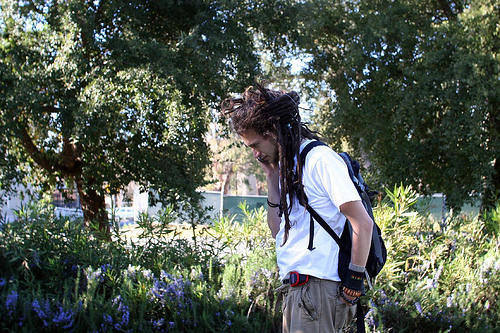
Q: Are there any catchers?
A: No, there are no catchers.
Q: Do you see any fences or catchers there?
A: No, there are no catchers or fences.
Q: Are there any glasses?
A: No, there are no glasses.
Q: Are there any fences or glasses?
A: No, there are no glasses or fences.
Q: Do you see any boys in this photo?
A: No, there are no boys.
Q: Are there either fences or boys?
A: No, there are no boys or fences.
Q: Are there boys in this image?
A: No, there are no boys.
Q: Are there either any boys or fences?
A: No, there are no boys or fences.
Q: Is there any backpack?
A: Yes, there is a backpack.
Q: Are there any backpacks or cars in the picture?
A: Yes, there is a backpack.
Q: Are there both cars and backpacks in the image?
A: No, there is a backpack but no cars.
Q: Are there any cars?
A: No, there are no cars.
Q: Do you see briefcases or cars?
A: No, there are no cars or briefcases.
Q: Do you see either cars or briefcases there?
A: No, there are no cars or briefcases.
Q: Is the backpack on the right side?
A: Yes, the backpack is on the right of the image.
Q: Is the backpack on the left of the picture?
A: No, the backpack is on the right of the image.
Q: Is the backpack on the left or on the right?
A: The backpack is on the right of the image.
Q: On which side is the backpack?
A: The backpack is on the right of the image.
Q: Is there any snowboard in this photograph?
A: No, there are no snowboards.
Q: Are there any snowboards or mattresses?
A: No, there are no snowboards or mattresses.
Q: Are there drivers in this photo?
A: No, there are no drivers.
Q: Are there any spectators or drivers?
A: No, there are no drivers or spectators.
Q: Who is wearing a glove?
A: The man is wearing a glove.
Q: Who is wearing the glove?
A: The man is wearing a glove.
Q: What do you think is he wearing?
A: The man is wearing a glove.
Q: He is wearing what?
A: The man is wearing a glove.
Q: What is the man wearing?
A: The man is wearing a glove.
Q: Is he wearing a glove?
A: Yes, the man is wearing a glove.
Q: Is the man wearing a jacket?
A: No, the man is wearing a glove.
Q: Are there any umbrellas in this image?
A: No, there are no umbrellas.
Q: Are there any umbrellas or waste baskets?
A: No, there are no umbrellas or waste baskets.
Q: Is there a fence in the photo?
A: No, there are no fences.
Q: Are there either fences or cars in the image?
A: No, there are no fences or cars.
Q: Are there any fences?
A: No, there are no fences.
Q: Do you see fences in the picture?
A: No, there are no fences.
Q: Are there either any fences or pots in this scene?
A: No, there are no fences or pots.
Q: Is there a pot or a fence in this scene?
A: No, there are no fences or pots.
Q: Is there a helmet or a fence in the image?
A: No, there are no fences or helmets.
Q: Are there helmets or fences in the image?
A: No, there are no fences or helmets.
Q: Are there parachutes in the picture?
A: No, there are no parachutes.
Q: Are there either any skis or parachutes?
A: No, there are no parachutes or skis.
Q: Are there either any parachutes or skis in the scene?
A: No, there are no parachutes or skis.